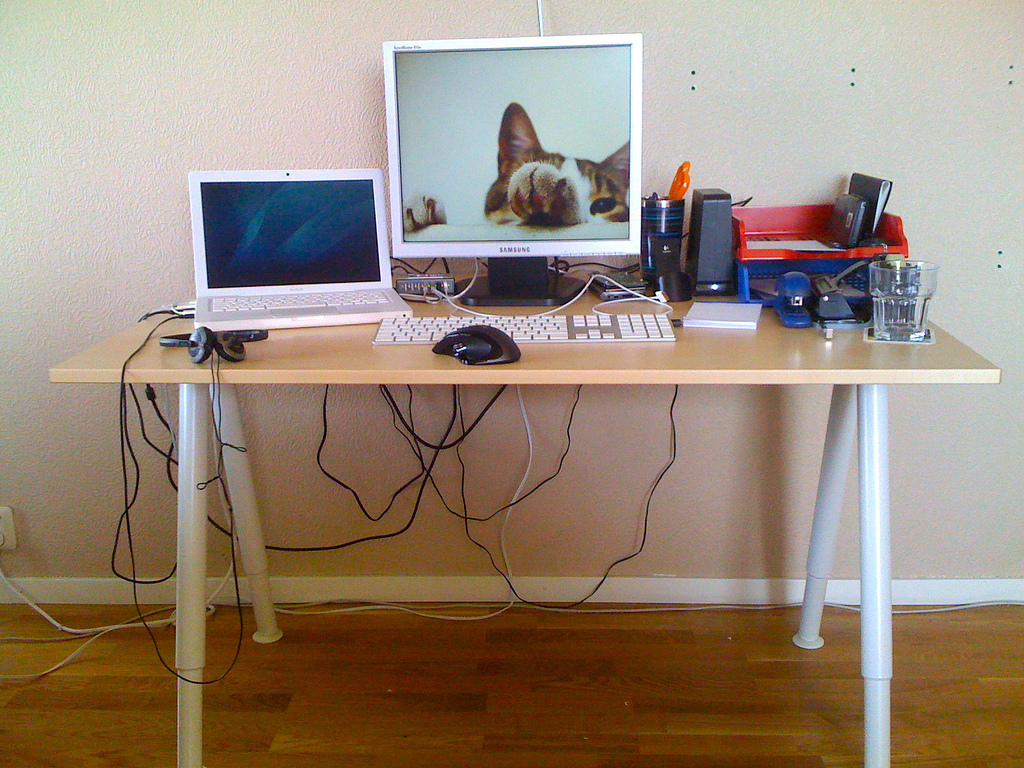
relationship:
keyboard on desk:
[371, 309, 681, 348] [52, 307, 1012, 765]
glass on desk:
[857, 253, 950, 346] [52, 307, 1012, 765]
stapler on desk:
[767, 270, 822, 337] [52, 307, 1012, 765]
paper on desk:
[689, 306, 755, 326] [52, 307, 1012, 765]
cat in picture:
[401, 99, 633, 233] [392, 43, 632, 245]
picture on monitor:
[392, 43, 632, 245] [379, 31, 650, 259]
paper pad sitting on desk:
[675, 294, 768, 340] [52, 307, 1012, 765]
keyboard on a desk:
[370, 310, 680, 349] [713, 319, 800, 358]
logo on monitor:
[496, 242, 536, 260] [374, 19, 649, 272]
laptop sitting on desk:
[184, 166, 414, 330] [93, 339, 416, 443]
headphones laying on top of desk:
[143, 313, 269, 398] [78, 341, 120, 465]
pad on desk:
[672, 287, 768, 339] [52, 307, 1012, 765]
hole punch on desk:
[806, 246, 869, 327] [39, 302, 1003, 406]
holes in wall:
[676, 60, 709, 104] [657, 12, 772, 149]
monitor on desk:
[374, 19, 649, 272] [52, 307, 1012, 765]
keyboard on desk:
[370, 310, 680, 349] [73, 243, 992, 654]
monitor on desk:
[379, 31, 650, 259] [46, 287, 1016, 767]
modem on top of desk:
[395, 261, 476, 303] [292, 330, 411, 408]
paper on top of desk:
[685, 274, 766, 346] [112, 349, 962, 406]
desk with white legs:
[46, 287, 1016, 767] [97, 514, 919, 666]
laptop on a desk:
[177, 263, 433, 384] [154, 308, 498, 423]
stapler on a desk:
[772, 271, 814, 328] [573, 373, 973, 378]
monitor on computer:
[379, 31, 650, 259] [469, 233, 662, 326]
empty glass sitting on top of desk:
[828, 248, 937, 393] [141, 213, 976, 522]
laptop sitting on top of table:
[184, 166, 414, 330] [46, 307, 984, 765]